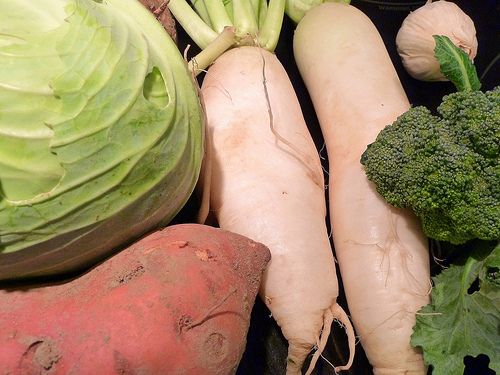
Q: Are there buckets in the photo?
A: No, there are no buckets.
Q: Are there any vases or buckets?
A: No, there are no buckets or vases.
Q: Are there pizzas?
A: No, there are no pizzas.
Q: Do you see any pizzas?
A: No, there are no pizzas.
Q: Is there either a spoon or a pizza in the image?
A: No, there are no pizzas or spoons.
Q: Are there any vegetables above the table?
A: Yes, there is a vegetable above the table.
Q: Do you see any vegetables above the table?
A: Yes, there is a vegetable above the table.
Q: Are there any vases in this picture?
A: No, there are no vases.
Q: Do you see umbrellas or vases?
A: No, there are no vases or umbrellas.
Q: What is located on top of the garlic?
A: The leaf is on top of the garlic.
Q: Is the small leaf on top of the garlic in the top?
A: Yes, the leaf is on top of the garlic.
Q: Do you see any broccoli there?
A: Yes, there is broccoli.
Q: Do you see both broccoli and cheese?
A: No, there is broccoli but no cheese.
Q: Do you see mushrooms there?
A: No, there are no mushrooms.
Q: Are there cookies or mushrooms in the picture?
A: No, there are no mushrooms or cookies.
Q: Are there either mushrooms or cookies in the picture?
A: No, there are no mushrooms or cookies.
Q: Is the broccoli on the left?
A: No, the broccoli is on the right of the image.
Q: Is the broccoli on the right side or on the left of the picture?
A: The broccoli is on the right of the image.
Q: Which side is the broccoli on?
A: The broccoli is on the right of the image.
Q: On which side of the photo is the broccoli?
A: The broccoli is on the right of the image.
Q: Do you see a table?
A: Yes, there is a table.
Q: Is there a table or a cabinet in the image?
A: Yes, there is a table.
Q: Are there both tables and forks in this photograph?
A: No, there is a table but no forks.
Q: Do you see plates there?
A: No, there are no plates.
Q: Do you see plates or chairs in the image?
A: No, there are no plates or chairs.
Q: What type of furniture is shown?
A: The furniture is a table.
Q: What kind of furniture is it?
A: The piece of furniture is a table.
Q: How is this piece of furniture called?
A: This is a table.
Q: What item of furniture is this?
A: This is a table.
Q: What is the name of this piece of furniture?
A: This is a table.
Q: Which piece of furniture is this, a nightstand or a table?
A: This is a table.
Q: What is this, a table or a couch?
A: This is a table.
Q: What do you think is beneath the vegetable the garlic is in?
A: The table is beneath the vegetable.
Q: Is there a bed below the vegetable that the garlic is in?
A: No, there is a table below the vegetable.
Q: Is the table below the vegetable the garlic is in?
A: Yes, the table is below the vegetable.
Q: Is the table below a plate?
A: No, the table is below the vegetable.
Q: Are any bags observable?
A: No, there are no bags.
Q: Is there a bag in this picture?
A: No, there are no bags.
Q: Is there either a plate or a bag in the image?
A: No, there are no bags or plates.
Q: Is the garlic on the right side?
A: Yes, the garlic is on the right of the image.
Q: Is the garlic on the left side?
A: No, the garlic is on the right of the image.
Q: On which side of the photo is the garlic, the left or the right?
A: The garlic is on the right of the image.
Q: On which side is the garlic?
A: The garlic is on the right of the image.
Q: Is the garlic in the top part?
A: Yes, the garlic is in the top of the image.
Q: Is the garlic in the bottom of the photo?
A: No, the garlic is in the top of the image.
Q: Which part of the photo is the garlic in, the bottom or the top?
A: The garlic is in the top of the image.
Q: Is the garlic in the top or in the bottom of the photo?
A: The garlic is in the top of the image.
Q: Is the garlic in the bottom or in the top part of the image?
A: The garlic is in the top of the image.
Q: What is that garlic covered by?
A: The garlic is covered by the leaves.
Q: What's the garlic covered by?
A: The garlic is covered by the leaves.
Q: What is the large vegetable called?
A: The vegetable is a sweet potato.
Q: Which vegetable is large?
A: The vegetable is a sweet potato.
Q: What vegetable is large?
A: The vegetable is a sweet potato.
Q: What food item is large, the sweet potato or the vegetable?
A: The sweet potato is large.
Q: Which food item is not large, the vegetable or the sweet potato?
A: The vegetable is not large.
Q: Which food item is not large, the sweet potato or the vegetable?
A: The vegetable is not large.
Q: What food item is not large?
A: The food item is a vegetable.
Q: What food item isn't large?
A: The food item is a vegetable.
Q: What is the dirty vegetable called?
A: The vegetable is a sweet potato.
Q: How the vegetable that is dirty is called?
A: The vegetable is a sweet potato.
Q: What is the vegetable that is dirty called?
A: The vegetable is a sweet potato.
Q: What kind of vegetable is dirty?
A: The vegetable is a sweet potato.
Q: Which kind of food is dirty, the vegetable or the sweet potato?
A: The sweet potato is dirty.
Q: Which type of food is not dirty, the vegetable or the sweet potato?
A: The vegetable is not dirty.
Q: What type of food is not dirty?
A: The food is a vegetable.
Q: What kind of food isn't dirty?
A: The food is a vegetable.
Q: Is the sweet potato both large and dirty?
A: Yes, the sweet potato is large and dirty.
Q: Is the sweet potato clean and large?
A: No, the sweet potato is large but dirty.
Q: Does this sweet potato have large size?
A: Yes, the sweet potato is large.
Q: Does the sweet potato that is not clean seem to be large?
A: Yes, the sweet potato is large.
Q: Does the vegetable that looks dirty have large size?
A: Yes, the sweet potato is large.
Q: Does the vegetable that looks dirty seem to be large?
A: Yes, the sweet potato is large.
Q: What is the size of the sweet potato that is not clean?
A: The sweet potato is large.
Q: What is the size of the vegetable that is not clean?
A: The sweet potato is large.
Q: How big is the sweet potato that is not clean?
A: The sweet potato is large.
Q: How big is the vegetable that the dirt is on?
A: The sweet potato is large.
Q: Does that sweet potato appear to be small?
A: No, the sweet potato is large.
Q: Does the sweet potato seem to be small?
A: No, the sweet potato is large.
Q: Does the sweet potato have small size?
A: No, the sweet potato is large.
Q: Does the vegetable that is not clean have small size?
A: No, the sweet potato is large.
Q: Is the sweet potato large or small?
A: The sweet potato is large.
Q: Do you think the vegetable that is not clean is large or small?
A: The sweet potato is large.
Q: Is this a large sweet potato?
A: Yes, this is a large sweet potato.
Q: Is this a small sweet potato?
A: No, this is a large sweet potato.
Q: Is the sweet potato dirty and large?
A: Yes, the sweet potato is dirty and large.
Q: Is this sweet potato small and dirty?
A: No, the sweet potato is dirty but large.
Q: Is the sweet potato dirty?
A: Yes, the sweet potato is dirty.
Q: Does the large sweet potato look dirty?
A: Yes, the sweet potato is dirty.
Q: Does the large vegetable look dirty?
A: Yes, the sweet potato is dirty.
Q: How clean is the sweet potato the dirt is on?
A: The sweet potato is dirty.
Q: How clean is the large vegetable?
A: The sweet potato is dirty.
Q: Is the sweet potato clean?
A: No, the sweet potato is dirty.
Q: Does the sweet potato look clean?
A: No, the sweet potato is dirty.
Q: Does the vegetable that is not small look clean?
A: No, the sweet potato is dirty.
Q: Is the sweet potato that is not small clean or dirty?
A: The sweet potato is dirty.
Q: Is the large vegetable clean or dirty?
A: The sweet potato is dirty.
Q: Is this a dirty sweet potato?
A: Yes, this is a dirty sweet potato.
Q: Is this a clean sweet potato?
A: No, this is a dirty sweet potato.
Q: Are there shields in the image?
A: No, there are no shields.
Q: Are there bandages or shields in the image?
A: No, there are no shields or bandages.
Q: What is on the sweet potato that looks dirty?
A: The dirt is on the sweet potato.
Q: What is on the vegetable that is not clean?
A: The dirt is on the sweet potato.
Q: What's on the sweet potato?
A: The dirt is on the sweet potato.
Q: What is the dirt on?
A: The dirt is on the sweet potato.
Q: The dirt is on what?
A: The dirt is on the sweet potato.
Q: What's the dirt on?
A: The dirt is on the sweet potato.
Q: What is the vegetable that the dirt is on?
A: The vegetable is a sweet potato.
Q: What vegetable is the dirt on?
A: The dirt is on the sweet potato.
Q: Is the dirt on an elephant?
A: No, the dirt is on a sweet potato.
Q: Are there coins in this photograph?
A: No, there are no coins.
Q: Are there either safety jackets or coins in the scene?
A: No, there are no coins or safety jackets.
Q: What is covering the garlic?
A: The leaves are covering the garlic.